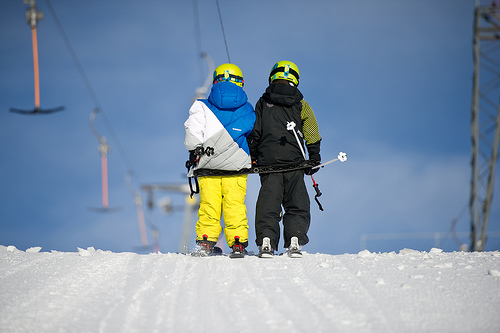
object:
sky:
[0, 1, 498, 258]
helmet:
[210, 60, 245, 87]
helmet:
[267, 62, 299, 84]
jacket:
[187, 81, 258, 171]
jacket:
[250, 87, 323, 168]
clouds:
[315, 145, 497, 232]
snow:
[1, 245, 499, 330]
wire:
[31, 0, 161, 198]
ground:
[0, 243, 497, 332]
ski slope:
[0, 248, 500, 333]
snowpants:
[198, 174, 252, 240]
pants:
[254, 171, 314, 248]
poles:
[285, 113, 326, 211]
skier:
[183, 62, 263, 261]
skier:
[244, 57, 327, 259]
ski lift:
[3, 3, 232, 257]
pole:
[311, 152, 347, 178]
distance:
[0, 0, 499, 250]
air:
[0, 0, 500, 333]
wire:
[214, 0, 246, 72]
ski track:
[163, 253, 194, 332]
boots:
[194, 239, 224, 256]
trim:
[202, 233, 243, 247]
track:
[87, 254, 148, 332]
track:
[322, 250, 393, 332]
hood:
[204, 80, 249, 112]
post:
[466, 2, 499, 244]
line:
[187, 0, 211, 96]